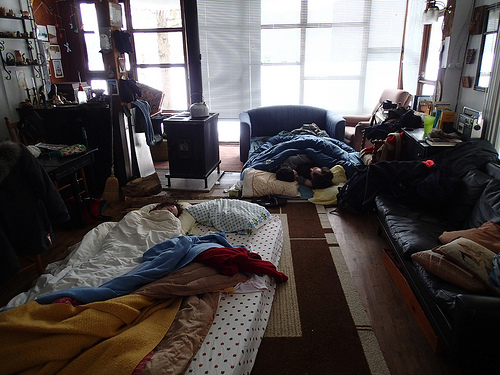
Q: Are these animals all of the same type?
A: Yes, all the animals are ducks.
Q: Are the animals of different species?
A: No, all the animals are ducks.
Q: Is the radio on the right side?
A: Yes, the radio is on the right of the image.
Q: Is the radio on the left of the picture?
A: No, the radio is on the right of the image.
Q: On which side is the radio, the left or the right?
A: The radio is on the right of the image.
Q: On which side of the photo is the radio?
A: The radio is on the right of the image.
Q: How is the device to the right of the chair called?
A: The device is a radio.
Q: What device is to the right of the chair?
A: The device is a radio.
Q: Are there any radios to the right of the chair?
A: Yes, there is a radio to the right of the chair.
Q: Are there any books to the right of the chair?
A: No, there is a radio to the right of the chair.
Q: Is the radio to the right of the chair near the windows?
A: Yes, the radio is to the right of the chair.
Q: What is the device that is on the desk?
A: The device is a radio.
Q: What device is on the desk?
A: The device is a radio.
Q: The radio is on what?
A: The radio is on the desk.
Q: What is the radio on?
A: The radio is on the desk.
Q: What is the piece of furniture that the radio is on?
A: The piece of furniture is a desk.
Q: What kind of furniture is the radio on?
A: The radio is on the desk.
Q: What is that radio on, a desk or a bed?
A: The radio is on a desk.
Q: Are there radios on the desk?
A: Yes, there is a radio on the desk.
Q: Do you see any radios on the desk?
A: Yes, there is a radio on the desk.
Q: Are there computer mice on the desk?
A: No, there is a radio on the desk.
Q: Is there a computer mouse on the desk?
A: No, there is a radio on the desk.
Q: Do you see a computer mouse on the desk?
A: No, there is a radio on the desk.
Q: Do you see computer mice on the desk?
A: No, there is a radio on the desk.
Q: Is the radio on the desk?
A: Yes, the radio is on the desk.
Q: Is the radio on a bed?
A: No, the radio is on the desk.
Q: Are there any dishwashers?
A: No, there are no dishwashers.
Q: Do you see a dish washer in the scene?
A: No, there are no dishwashers.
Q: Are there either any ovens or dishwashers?
A: No, there are no dishwashers or ovens.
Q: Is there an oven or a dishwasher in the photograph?
A: No, there are no dishwashers or ovens.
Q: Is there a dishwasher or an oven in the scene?
A: No, there are no dishwashers or ovens.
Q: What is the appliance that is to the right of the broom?
A: The appliance is a stove.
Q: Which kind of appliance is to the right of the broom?
A: The appliance is a stove.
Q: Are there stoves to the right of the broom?
A: Yes, there is a stove to the right of the broom.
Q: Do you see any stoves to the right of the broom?
A: Yes, there is a stove to the right of the broom.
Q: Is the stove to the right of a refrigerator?
A: No, the stove is to the right of a broom.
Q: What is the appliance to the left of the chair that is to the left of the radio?
A: The appliance is a stove.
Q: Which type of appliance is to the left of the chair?
A: The appliance is a stove.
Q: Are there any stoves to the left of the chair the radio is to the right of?
A: Yes, there is a stove to the left of the chair.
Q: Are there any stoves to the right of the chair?
A: No, the stove is to the left of the chair.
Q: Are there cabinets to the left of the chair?
A: No, there is a stove to the left of the chair.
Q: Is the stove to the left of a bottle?
A: No, the stove is to the left of the chair.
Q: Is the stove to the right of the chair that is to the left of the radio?
A: No, the stove is to the left of the chair.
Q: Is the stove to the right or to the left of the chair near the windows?
A: The stove is to the left of the chair.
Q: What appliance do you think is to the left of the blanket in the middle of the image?
A: The appliance is a stove.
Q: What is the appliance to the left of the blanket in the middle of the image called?
A: The appliance is a stove.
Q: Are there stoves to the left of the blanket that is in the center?
A: Yes, there is a stove to the left of the blanket.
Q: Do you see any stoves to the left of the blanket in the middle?
A: Yes, there is a stove to the left of the blanket.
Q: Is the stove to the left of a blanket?
A: Yes, the stove is to the left of a blanket.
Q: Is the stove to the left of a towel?
A: No, the stove is to the left of a blanket.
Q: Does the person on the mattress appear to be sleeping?
A: Yes, the person is sleeping.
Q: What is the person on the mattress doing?
A: The person is sleeping.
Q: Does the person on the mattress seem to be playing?
A: No, the person is sleeping.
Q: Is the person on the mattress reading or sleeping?
A: The person is sleeping.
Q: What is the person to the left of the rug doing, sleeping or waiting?
A: The person is sleeping.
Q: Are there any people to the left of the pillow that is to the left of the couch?
A: Yes, there is a person to the left of the pillow.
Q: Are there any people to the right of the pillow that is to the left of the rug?
A: No, the person is to the left of the pillow.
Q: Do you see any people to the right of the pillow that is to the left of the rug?
A: No, the person is to the left of the pillow.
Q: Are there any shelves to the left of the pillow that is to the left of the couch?
A: No, there is a person to the left of the pillow.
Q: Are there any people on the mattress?
A: Yes, there is a person on the mattress.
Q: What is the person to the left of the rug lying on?
A: The person is lying on the mattress.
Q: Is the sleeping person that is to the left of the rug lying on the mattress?
A: Yes, the person is lying on the mattress.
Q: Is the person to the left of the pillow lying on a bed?
A: No, the person is lying on the mattress.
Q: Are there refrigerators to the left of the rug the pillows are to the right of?
A: No, there is a person to the left of the rug.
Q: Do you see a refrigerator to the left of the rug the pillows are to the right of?
A: No, there is a person to the left of the rug.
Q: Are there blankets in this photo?
A: Yes, there is a blanket.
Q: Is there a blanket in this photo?
A: Yes, there is a blanket.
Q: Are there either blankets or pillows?
A: Yes, there is a blanket.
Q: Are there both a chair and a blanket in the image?
A: Yes, there are both a blanket and a chair.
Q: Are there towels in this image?
A: No, there are no towels.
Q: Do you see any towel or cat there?
A: No, there are no towels or cats.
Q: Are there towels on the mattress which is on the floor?
A: No, there is a blanket on the mattress.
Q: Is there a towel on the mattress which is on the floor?
A: No, there is a blanket on the mattress.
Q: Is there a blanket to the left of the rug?
A: Yes, there is a blanket to the left of the rug.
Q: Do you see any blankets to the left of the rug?
A: Yes, there is a blanket to the left of the rug.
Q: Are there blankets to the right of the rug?
A: No, the blanket is to the left of the rug.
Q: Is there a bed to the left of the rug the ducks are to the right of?
A: No, there is a blanket to the left of the rug.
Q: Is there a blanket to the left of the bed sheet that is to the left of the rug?
A: Yes, there is a blanket to the left of the bed sheet.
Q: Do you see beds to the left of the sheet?
A: No, there is a blanket to the left of the sheet.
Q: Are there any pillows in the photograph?
A: Yes, there are pillows.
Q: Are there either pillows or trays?
A: Yes, there are pillows.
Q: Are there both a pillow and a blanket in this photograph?
A: Yes, there are both a pillow and a blanket.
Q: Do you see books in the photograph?
A: No, there are no books.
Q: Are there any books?
A: No, there are no books.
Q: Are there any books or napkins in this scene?
A: No, there are no books or napkins.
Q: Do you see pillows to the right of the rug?
A: Yes, there are pillows to the right of the rug.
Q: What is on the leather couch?
A: The pillows are on the couch.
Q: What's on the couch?
A: The pillows are on the couch.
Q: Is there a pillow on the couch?
A: Yes, there are pillows on the couch.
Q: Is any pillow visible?
A: Yes, there is a pillow.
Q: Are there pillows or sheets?
A: Yes, there is a pillow.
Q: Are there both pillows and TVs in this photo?
A: No, there is a pillow but no televisions.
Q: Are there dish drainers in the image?
A: No, there are no dish drainers.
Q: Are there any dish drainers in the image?
A: No, there are no dish drainers.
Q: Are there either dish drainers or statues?
A: No, there are no dish drainers or statues.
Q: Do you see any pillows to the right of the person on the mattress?
A: Yes, there is a pillow to the right of the person.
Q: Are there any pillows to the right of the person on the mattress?
A: Yes, there is a pillow to the right of the person.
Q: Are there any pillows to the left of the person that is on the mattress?
A: No, the pillow is to the right of the person.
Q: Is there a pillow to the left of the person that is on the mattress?
A: No, the pillow is to the right of the person.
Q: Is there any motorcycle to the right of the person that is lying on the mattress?
A: No, there is a pillow to the right of the person.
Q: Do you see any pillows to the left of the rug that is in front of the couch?
A: Yes, there is a pillow to the left of the rug.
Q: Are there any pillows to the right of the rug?
A: No, the pillow is to the left of the rug.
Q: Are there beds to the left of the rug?
A: No, there is a pillow to the left of the rug.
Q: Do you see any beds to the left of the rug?
A: No, there is a pillow to the left of the rug.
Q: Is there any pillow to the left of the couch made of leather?
A: Yes, there is a pillow to the left of the couch.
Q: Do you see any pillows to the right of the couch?
A: No, the pillow is to the left of the couch.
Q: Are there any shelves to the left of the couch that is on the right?
A: No, there is a pillow to the left of the couch.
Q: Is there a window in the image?
A: Yes, there are windows.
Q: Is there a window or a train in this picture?
A: Yes, there are windows.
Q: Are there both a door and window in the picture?
A: No, there are windows but no doors.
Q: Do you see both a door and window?
A: No, there are windows but no doors.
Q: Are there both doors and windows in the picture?
A: No, there are windows but no doors.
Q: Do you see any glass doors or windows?
A: Yes, there are glass windows.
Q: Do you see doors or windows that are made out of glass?
A: Yes, the windows are made of glass.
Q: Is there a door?
A: No, there are no doors.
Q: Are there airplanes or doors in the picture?
A: No, there are no doors or airplanes.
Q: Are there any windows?
A: Yes, there are windows.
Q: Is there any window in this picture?
A: Yes, there are windows.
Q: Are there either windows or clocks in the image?
A: Yes, there are windows.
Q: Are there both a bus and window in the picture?
A: No, there are windows but no buses.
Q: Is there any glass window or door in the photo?
A: Yes, there are glass windows.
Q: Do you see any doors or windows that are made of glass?
A: Yes, the windows are made of glass.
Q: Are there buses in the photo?
A: No, there are no buses.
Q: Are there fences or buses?
A: No, there are no buses or fences.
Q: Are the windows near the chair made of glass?
A: Yes, the windows are made of glass.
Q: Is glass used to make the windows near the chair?
A: Yes, the windows are made of glass.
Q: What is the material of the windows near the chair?
A: The windows are made of glass.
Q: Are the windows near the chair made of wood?
A: No, the windows are made of glass.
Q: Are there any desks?
A: Yes, there is a desk.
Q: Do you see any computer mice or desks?
A: Yes, there is a desk.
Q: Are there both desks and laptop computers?
A: No, there is a desk but no laptops.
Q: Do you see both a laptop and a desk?
A: No, there is a desk but no laptops.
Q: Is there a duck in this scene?
A: Yes, there are ducks.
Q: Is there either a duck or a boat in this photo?
A: Yes, there are ducks.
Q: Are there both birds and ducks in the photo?
A: No, there are ducks but no birds.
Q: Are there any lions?
A: No, there are no lions.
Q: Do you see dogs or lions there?
A: No, there are no lions or dogs.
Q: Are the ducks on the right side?
A: Yes, the ducks are on the right of the image.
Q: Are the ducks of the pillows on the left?
A: No, the ducks are on the right of the image.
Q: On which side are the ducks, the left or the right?
A: The ducks are on the right of the image.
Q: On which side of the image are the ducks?
A: The ducks are on the right of the image.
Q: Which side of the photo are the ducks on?
A: The ducks are on the right of the image.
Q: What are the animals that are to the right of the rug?
A: The animals are ducks.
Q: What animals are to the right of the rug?
A: The animals are ducks.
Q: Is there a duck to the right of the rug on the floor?
A: Yes, there are ducks to the right of the rug.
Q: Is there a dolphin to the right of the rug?
A: No, there are ducks to the right of the rug.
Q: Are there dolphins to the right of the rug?
A: No, there are ducks to the right of the rug.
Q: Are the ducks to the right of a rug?
A: Yes, the ducks are to the right of a rug.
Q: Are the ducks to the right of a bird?
A: No, the ducks are to the right of a rug.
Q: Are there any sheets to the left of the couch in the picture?
A: Yes, there is a sheet to the left of the couch.